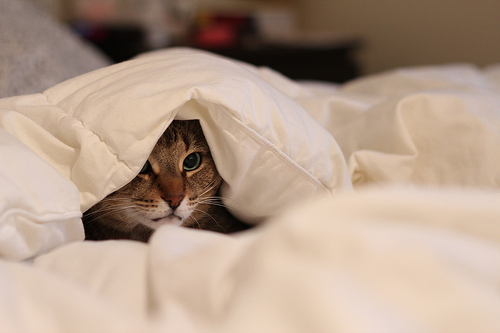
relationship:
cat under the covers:
[116, 114, 219, 231] [22, 63, 414, 303]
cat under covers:
[49, 87, 284, 258] [14, 74, 321, 190]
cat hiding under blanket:
[85, 115, 230, 245] [257, 101, 443, 284]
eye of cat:
[178, 147, 208, 179] [97, 112, 229, 241]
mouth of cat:
[127, 192, 204, 250] [59, 65, 259, 247]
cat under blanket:
[134, 125, 224, 221] [1, 31, 498, 330]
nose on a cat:
[154, 177, 196, 210] [81, 117, 226, 234]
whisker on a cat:
[83, 202, 136, 217] [81, 117, 226, 234]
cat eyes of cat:
[127, 149, 214, 178] [71, 103, 269, 260]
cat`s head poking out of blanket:
[82, 116, 246, 242] [0, 44, 499, 261]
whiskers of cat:
[89, 188, 268, 230] [26, 92, 315, 269]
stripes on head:
[160, 116, 200, 155] [97, 120, 219, 245]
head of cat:
[97, 120, 219, 245] [69, 103, 255, 238]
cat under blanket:
[85, 115, 230, 245] [1, 31, 498, 330]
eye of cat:
[162, 120, 227, 189] [53, 62, 261, 263]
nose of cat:
[154, 177, 196, 210] [88, 85, 248, 246]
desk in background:
[167, 32, 369, 83] [93, 2, 498, 73]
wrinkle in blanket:
[342, 85, 492, 188] [1, 31, 498, 330]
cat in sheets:
[80, 118, 258, 244] [223, 65, 488, 278]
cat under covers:
[81, 113, 245, 246] [0, 36, 497, 330]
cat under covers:
[85, 115, 230, 245] [2, 36, 498, 264]